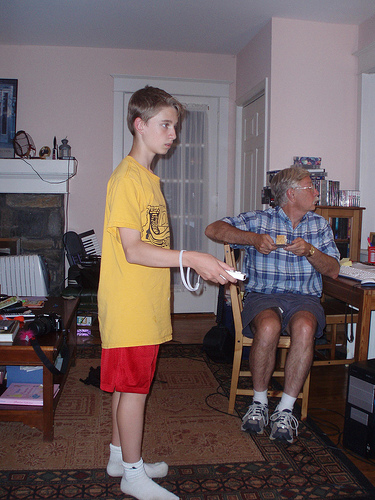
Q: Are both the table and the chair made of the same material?
A: Yes, both the table and the chair are made of wood.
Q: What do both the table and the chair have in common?
A: The material, both the table and the chair are wooden.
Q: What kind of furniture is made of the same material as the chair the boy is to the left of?
A: The table is made of the same material as the chair.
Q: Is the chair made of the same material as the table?
A: Yes, both the chair and the table are made of wood.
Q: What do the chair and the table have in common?
A: The material, both the chair and the table are wooden.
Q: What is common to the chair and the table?
A: The material, both the chair and the table are wooden.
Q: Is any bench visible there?
A: No, there are no benches.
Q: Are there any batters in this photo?
A: No, there are no batters.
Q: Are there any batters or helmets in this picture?
A: No, there are no batters or helmets.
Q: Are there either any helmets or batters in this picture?
A: No, there are no batters or helmets.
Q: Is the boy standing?
A: Yes, the boy is standing.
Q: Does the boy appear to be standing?
A: Yes, the boy is standing.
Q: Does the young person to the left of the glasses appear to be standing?
A: Yes, the boy is standing.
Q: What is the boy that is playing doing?
A: The boy is standing.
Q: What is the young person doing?
A: The boy is standing.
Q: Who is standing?
A: The boy is standing.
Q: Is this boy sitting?
A: No, the boy is standing.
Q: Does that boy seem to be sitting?
A: No, the boy is standing.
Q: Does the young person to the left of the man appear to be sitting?
A: No, the boy is standing.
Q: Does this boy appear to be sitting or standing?
A: The boy is standing.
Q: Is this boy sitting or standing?
A: The boy is standing.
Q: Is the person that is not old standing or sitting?
A: The boy is standing.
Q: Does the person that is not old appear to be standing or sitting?
A: The boy is standing.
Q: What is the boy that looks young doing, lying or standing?
A: The boy is standing.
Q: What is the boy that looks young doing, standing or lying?
A: The boy is standing.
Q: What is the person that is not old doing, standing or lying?
A: The boy is standing.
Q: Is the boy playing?
A: Yes, the boy is playing.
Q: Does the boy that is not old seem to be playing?
A: Yes, the boy is playing.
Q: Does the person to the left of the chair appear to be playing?
A: Yes, the boy is playing.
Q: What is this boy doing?
A: The boy is playing.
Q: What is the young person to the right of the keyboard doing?
A: The boy is playing.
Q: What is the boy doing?
A: The boy is playing.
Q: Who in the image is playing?
A: The boy is playing.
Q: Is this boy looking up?
A: No, the boy is playing.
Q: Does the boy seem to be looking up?
A: No, the boy is playing.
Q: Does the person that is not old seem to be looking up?
A: No, the boy is playing.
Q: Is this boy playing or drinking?
A: The boy is playing.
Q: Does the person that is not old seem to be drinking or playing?
A: The boy is playing.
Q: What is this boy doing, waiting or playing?
A: The boy is playing.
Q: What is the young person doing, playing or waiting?
A: The boy is playing.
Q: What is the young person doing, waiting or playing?
A: The boy is playing.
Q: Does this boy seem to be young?
A: Yes, the boy is young.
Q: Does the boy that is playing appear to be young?
A: Yes, the boy is young.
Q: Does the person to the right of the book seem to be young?
A: Yes, the boy is young.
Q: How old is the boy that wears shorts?
A: The boy is young.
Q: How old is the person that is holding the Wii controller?
A: The boy is young.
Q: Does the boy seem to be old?
A: No, the boy is young.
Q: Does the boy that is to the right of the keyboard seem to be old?
A: No, the boy is young.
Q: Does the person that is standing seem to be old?
A: No, the boy is young.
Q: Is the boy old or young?
A: The boy is young.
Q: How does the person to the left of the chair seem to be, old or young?
A: The boy is young.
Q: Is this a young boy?
A: Yes, this is a young boy.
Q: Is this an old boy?
A: No, this is a young boy.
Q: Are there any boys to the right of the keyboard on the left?
A: Yes, there is a boy to the right of the keyboard.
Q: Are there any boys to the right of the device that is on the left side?
A: Yes, there is a boy to the right of the keyboard.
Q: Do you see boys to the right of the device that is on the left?
A: Yes, there is a boy to the right of the keyboard.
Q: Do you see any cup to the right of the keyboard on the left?
A: No, there is a boy to the right of the keyboard.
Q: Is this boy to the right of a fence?
A: No, the boy is to the right of the keyboard.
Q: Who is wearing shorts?
A: The boy is wearing shorts.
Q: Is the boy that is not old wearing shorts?
A: Yes, the boy is wearing shorts.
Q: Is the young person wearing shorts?
A: Yes, the boy is wearing shorts.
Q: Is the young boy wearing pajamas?
A: No, the boy is wearing shorts.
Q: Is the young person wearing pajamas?
A: No, the boy is wearing shorts.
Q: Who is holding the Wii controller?
A: The boy is holding the Wii controller.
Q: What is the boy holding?
A: The boy is holding the Wii remotes.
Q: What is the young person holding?
A: The boy is holding the Wii remotes.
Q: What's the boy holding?
A: The boy is holding the Wii remotes.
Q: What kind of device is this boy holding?
A: The boy is holding the Wii controller.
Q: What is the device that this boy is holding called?
A: The device is a Wii controller.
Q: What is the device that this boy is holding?
A: The device is a Wii controller.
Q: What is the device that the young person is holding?
A: The device is a Wii controller.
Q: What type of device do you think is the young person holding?
A: The boy is holding the Wii controller.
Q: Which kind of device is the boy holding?
A: The boy is holding the Wii controller.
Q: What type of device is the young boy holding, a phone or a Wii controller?
A: The boy is holding a Wii controller.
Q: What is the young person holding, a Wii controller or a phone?
A: The boy is holding a Wii controller.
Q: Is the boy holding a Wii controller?
A: Yes, the boy is holding a Wii controller.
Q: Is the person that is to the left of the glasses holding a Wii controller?
A: Yes, the boy is holding a Wii controller.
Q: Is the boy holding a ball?
A: No, the boy is holding a Wii controller.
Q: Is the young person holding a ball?
A: No, the boy is holding a Wii controller.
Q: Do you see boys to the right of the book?
A: Yes, there is a boy to the right of the book.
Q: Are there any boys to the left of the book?
A: No, the boy is to the right of the book.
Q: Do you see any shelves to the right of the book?
A: No, there is a boy to the right of the book.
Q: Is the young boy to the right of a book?
A: Yes, the boy is to the right of a book.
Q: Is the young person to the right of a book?
A: Yes, the boy is to the right of a book.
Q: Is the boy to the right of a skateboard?
A: No, the boy is to the right of a book.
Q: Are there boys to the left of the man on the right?
A: Yes, there is a boy to the left of the man.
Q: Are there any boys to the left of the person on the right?
A: Yes, there is a boy to the left of the man.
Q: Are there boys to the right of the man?
A: No, the boy is to the left of the man.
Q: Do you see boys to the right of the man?
A: No, the boy is to the left of the man.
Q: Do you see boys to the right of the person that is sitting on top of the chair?
A: No, the boy is to the left of the man.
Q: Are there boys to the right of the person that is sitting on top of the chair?
A: No, the boy is to the left of the man.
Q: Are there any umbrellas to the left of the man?
A: No, there is a boy to the left of the man.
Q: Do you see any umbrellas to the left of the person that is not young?
A: No, there is a boy to the left of the man.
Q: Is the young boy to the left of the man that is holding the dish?
A: Yes, the boy is to the left of the man.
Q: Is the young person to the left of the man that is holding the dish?
A: Yes, the boy is to the left of the man.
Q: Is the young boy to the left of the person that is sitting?
A: Yes, the boy is to the left of the man.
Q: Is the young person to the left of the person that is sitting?
A: Yes, the boy is to the left of the man.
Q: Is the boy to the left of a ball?
A: No, the boy is to the left of the man.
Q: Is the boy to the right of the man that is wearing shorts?
A: No, the boy is to the left of the man.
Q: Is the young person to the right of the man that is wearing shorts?
A: No, the boy is to the left of the man.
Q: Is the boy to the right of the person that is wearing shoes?
A: No, the boy is to the left of the man.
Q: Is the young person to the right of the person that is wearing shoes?
A: No, the boy is to the left of the man.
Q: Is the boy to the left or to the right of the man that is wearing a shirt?
A: The boy is to the left of the man.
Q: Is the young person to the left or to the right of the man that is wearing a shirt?
A: The boy is to the left of the man.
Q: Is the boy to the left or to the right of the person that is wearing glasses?
A: The boy is to the left of the man.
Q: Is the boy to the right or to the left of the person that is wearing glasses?
A: The boy is to the left of the man.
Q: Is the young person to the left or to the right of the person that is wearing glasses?
A: The boy is to the left of the man.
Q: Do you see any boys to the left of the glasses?
A: Yes, there is a boy to the left of the glasses.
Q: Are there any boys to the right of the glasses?
A: No, the boy is to the left of the glasses.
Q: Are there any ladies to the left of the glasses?
A: No, there is a boy to the left of the glasses.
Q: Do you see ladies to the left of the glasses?
A: No, there is a boy to the left of the glasses.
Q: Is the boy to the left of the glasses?
A: Yes, the boy is to the left of the glasses.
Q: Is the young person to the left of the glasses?
A: Yes, the boy is to the left of the glasses.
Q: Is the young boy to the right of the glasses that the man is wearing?
A: No, the boy is to the left of the glasses.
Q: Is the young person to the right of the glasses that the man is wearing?
A: No, the boy is to the left of the glasses.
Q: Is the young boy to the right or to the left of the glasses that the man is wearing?
A: The boy is to the left of the glasses.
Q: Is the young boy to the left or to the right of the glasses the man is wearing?
A: The boy is to the left of the glasses.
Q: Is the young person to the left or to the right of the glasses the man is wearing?
A: The boy is to the left of the glasses.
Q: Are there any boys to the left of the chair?
A: Yes, there is a boy to the left of the chair.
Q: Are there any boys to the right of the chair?
A: No, the boy is to the left of the chair.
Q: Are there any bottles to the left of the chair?
A: No, there is a boy to the left of the chair.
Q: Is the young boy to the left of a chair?
A: Yes, the boy is to the left of a chair.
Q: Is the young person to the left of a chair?
A: Yes, the boy is to the left of a chair.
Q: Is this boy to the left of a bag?
A: No, the boy is to the left of a chair.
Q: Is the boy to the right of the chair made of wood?
A: No, the boy is to the left of the chair.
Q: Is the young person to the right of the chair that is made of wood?
A: No, the boy is to the left of the chair.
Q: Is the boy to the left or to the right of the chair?
A: The boy is to the left of the chair.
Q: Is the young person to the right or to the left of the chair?
A: The boy is to the left of the chair.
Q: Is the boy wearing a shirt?
A: Yes, the boy is wearing a shirt.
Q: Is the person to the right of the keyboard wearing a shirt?
A: Yes, the boy is wearing a shirt.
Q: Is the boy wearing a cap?
A: No, the boy is wearing a shirt.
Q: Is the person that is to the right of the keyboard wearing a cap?
A: No, the boy is wearing a shirt.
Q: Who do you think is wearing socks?
A: The boy is wearing socks.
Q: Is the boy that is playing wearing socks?
A: Yes, the boy is wearing socks.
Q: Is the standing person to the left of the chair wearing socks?
A: Yes, the boy is wearing socks.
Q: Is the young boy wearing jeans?
A: No, the boy is wearing socks.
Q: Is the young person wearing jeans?
A: No, the boy is wearing socks.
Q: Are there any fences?
A: No, there are no fences.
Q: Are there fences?
A: No, there are no fences.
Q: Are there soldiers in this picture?
A: No, there are no soldiers.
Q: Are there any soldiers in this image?
A: No, there are no soldiers.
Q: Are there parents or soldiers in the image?
A: No, there are no soldiers or parents.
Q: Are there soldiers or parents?
A: No, there are no soldiers or parents.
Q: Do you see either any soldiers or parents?
A: No, there are no soldiers or parents.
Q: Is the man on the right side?
A: Yes, the man is on the right of the image.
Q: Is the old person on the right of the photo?
A: Yes, the man is on the right of the image.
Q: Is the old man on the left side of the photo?
A: No, the man is on the right of the image.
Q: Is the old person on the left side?
A: No, the man is on the right of the image.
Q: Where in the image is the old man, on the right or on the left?
A: The man is on the right of the image.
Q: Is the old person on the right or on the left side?
A: The man is on the right of the image.